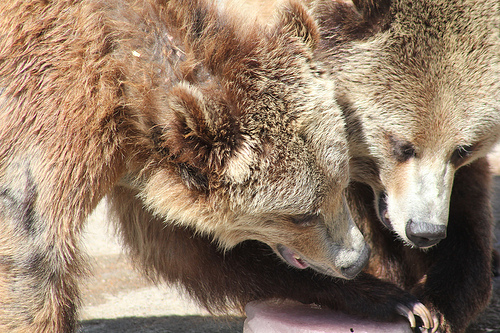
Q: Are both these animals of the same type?
A: Yes, all the animals are bears.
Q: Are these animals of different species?
A: No, all the animals are bears.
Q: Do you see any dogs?
A: No, there are no dogs.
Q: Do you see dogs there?
A: No, there are no dogs.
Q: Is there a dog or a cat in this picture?
A: No, there are no dogs or cats.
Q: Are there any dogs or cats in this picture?
A: No, there are no dogs or cats.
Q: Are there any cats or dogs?
A: No, there are no dogs or cats.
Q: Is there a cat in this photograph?
A: No, there are no cats.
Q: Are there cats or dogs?
A: No, there are no cats or dogs.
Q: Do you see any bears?
A: Yes, there is a bear.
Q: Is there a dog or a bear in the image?
A: Yes, there is a bear.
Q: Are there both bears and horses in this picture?
A: No, there is a bear but no horses.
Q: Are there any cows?
A: No, there are no cows.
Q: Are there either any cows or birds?
A: No, there are no cows or birds.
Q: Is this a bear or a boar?
A: This is a bear.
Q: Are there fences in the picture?
A: No, there are no fences.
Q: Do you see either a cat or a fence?
A: No, there are no fences or cats.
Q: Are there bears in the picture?
A: Yes, there is a bear.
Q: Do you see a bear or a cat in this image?
A: Yes, there is a bear.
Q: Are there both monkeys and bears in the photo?
A: No, there is a bear but no monkeys.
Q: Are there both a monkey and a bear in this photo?
A: No, there is a bear but no monkeys.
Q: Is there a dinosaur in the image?
A: No, there are no dinosaurs.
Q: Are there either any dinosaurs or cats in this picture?
A: No, there are no dinosaurs or cats.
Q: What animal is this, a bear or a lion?
A: This is a bear.